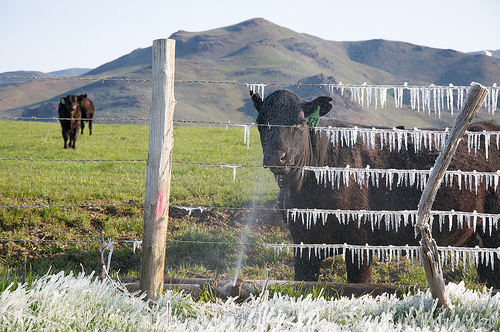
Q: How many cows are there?
A: Three.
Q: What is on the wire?
A: Ice.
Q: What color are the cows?
A: Brown.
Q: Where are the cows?
A: Pasture.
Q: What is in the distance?
A: Mountains.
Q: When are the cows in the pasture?
A: Daytime.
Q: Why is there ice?
A: Rain froze.